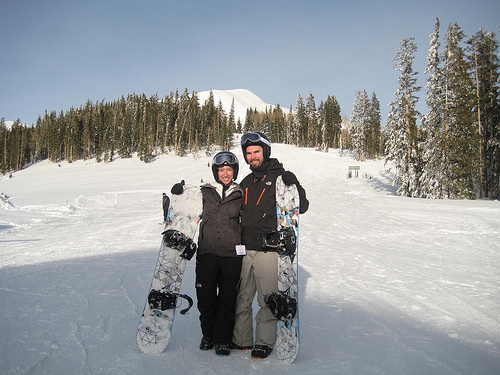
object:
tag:
[234, 243, 247, 255]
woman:
[170, 148, 245, 359]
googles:
[210, 149, 241, 166]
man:
[222, 129, 310, 361]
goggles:
[240, 130, 266, 147]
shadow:
[0, 247, 499, 374]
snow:
[0, 134, 499, 374]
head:
[237, 131, 270, 171]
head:
[209, 150, 238, 184]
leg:
[248, 252, 280, 348]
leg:
[230, 250, 254, 348]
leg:
[212, 256, 239, 345]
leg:
[193, 252, 219, 341]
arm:
[275, 165, 309, 215]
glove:
[167, 180, 184, 196]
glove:
[281, 168, 297, 186]